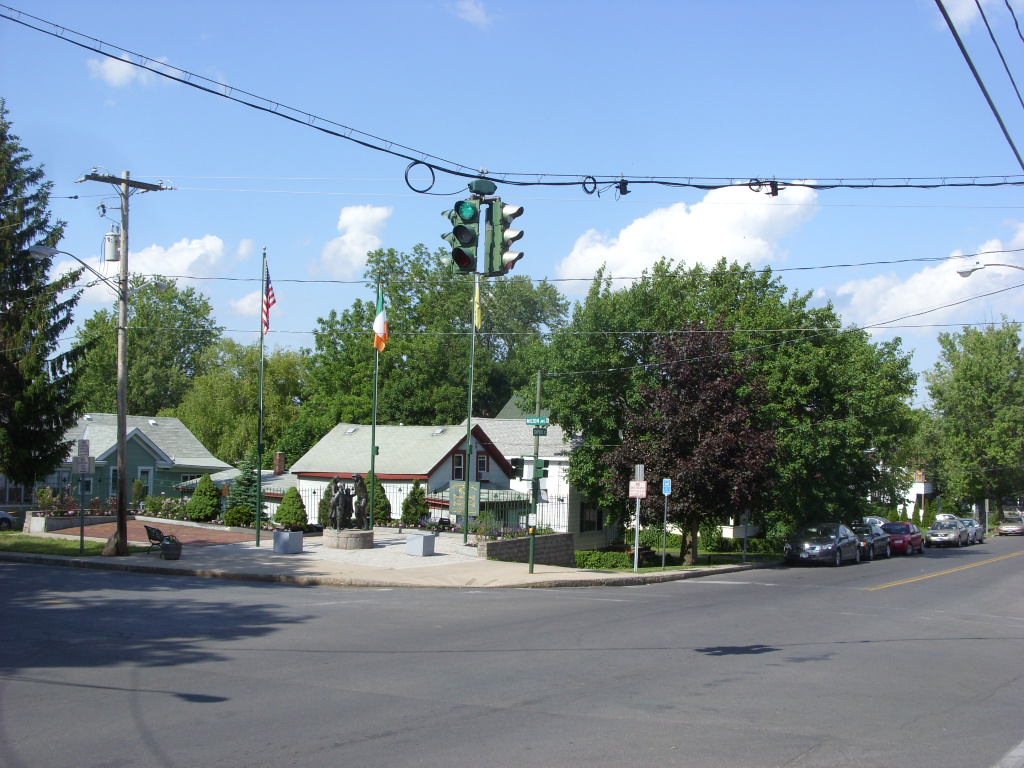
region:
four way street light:
[446, 177, 527, 275]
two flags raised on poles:
[252, 241, 392, 548]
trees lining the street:
[521, 257, 1019, 567]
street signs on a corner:
[522, 412, 552, 574]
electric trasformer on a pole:
[72, 164, 174, 551]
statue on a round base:
[318, 468, 377, 548]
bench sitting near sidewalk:
[138, 522, 181, 558]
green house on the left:
[2, 411, 233, 511]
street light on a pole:
[24, 241, 130, 559]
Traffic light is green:
[434, 187, 530, 285]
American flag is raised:
[247, 247, 283, 339]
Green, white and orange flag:
[361, 273, 397, 357]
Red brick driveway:
[58, 501, 264, 560]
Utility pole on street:
[64, 150, 173, 568]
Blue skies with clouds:
[0, 2, 1019, 410]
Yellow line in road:
[854, 542, 1019, 600]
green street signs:
[514, 406, 556, 438]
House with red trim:
[277, 411, 527, 552]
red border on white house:
[409, 409, 558, 515]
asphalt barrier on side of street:
[467, 505, 592, 598]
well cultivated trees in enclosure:
[161, 450, 378, 524]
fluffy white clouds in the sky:
[565, 169, 835, 299]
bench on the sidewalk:
[133, 504, 191, 553]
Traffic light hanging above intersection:
[439, 174, 528, 277]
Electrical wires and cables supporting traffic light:
[0, 3, 1019, 199]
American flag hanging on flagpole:
[252, 247, 278, 548]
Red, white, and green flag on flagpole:
[362, 272, 391, 536]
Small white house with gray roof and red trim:
[288, 417, 541, 532]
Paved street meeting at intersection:
[2, 533, 1023, 764]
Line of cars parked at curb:
[783, 511, 983, 570]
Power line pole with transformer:
[73, 167, 171, 557]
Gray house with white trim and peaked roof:
[9, 411, 229, 526]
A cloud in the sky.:
[324, 201, 383, 284]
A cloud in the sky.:
[101, 46, 232, 92]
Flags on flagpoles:
[239, 234, 489, 547]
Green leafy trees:
[1, 96, 1020, 543]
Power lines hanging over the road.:
[5, 3, 1020, 427]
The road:
[4, 532, 1017, 763]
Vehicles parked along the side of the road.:
[780, 512, 1019, 598]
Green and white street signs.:
[511, 415, 556, 436]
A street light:
[952, 262, 1020, 310]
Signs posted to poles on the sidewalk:
[624, 462, 688, 574]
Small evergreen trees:
[163, 465, 446, 542]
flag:
[334, 284, 412, 374]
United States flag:
[229, 243, 278, 336]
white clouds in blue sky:
[296, 173, 361, 262]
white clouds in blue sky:
[558, 195, 629, 252]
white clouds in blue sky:
[624, 226, 698, 278]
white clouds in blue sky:
[707, 201, 793, 260]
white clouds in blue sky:
[886, 257, 964, 331]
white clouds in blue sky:
[178, 239, 230, 291]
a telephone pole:
[83, 159, 167, 537]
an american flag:
[250, 244, 276, 328]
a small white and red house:
[288, 415, 513, 539]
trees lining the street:
[551, 276, 925, 584]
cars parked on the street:
[784, 506, 994, 561]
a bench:
[138, 519, 184, 552]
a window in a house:
[446, 453, 460, 473]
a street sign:
[70, 434, 93, 549]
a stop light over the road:
[447, 194, 520, 275]